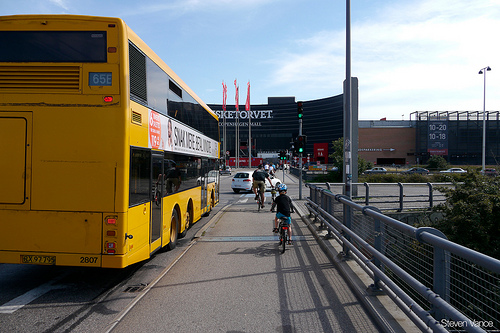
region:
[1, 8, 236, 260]
a large yellow bus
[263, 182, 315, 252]
a person riding a bike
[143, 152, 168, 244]
black rear bus door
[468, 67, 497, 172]
a tall light post in the distance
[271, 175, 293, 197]
bicyclist wearing a blue helmet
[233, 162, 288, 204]
a small white car in front of the bus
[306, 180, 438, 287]
a silver metal fence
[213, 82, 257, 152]
three red flags on flag poles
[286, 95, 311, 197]
two traffic signals on poles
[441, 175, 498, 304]
a leafy tree off of the over pass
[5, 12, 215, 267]
Yellow color double decker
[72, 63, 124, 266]
Number 65E number 2807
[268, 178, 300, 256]
Safety helmet worn bicyclist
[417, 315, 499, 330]
Watermark corner Steven Vance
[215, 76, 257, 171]
Three red flags tall poles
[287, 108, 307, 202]
Traffic lights shown green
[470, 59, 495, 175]
Street light high above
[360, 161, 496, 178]
Line of traffic background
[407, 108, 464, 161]
Large advertisement exterior building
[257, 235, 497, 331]
Metal bridge cast shadow road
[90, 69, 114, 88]
an identifier that reads 65E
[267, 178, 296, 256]
a kid that is bicycling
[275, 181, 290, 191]
a helmet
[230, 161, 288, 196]
a white car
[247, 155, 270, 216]
a bicyclist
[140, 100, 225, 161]
an advertisement on a bus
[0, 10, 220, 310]
a yellow bus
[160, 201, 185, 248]
one of the rear wheels of the bus that is about to make a right turn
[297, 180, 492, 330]
a fence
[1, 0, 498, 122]
the sky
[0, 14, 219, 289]
the bus is yellow in color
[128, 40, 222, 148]
the bus has black windows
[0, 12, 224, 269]
the bus is two level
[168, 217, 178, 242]
the rims are yellow in color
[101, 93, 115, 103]
the back light is red in color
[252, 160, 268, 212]
a man is riding a bicycle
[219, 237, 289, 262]
the cyclist is casting a shadow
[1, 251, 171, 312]
the bus is casting a shadow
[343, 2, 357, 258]
the pole is tall and grey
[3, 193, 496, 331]
the bus is crossing a bridge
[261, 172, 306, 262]
boy is riding bicycle